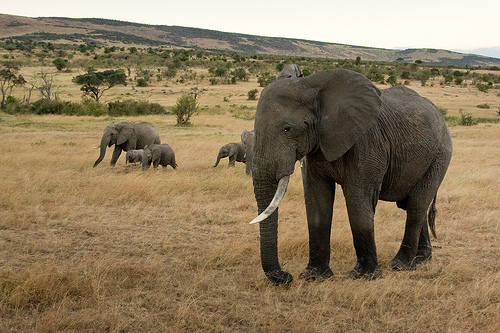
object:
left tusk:
[244, 171, 295, 228]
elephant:
[227, 56, 469, 288]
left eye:
[275, 122, 296, 135]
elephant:
[139, 141, 185, 175]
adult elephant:
[87, 116, 171, 171]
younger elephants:
[135, 141, 183, 174]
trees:
[67, 61, 133, 112]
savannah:
[0, 0, 497, 330]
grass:
[1, 136, 498, 332]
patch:
[0, 182, 244, 332]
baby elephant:
[123, 148, 145, 164]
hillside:
[0, 14, 497, 70]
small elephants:
[209, 137, 251, 172]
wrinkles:
[376, 100, 443, 163]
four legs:
[294, 178, 460, 297]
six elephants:
[87, 62, 454, 288]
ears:
[297, 62, 389, 167]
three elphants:
[88, 112, 185, 178]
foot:
[294, 260, 340, 287]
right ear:
[274, 61, 306, 80]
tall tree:
[0, 62, 32, 113]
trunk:
[245, 165, 300, 296]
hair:
[425, 204, 442, 241]